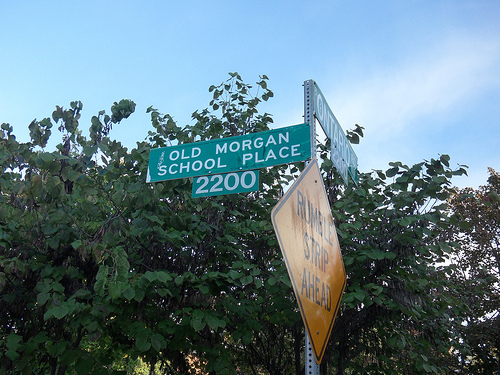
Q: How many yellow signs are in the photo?
A: One.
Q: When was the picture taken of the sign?
A: Daytime.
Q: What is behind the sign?
A: Trees.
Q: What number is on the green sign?
A: 2200.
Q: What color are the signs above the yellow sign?
A: Green.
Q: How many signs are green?
A: Two.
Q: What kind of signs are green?
A: Street.